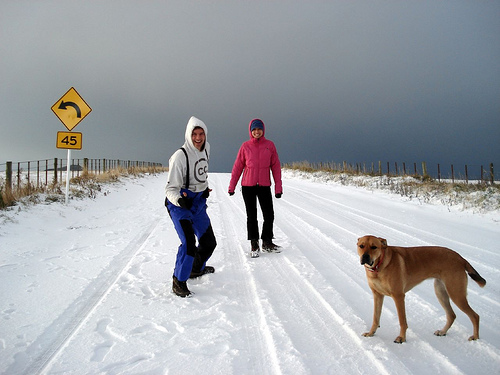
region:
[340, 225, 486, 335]
brown dog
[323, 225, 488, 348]
brown dog in white snow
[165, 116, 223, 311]
man standing in snow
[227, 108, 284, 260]
woman standing in snow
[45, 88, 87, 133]
yellow and black sign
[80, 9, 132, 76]
white clouds in blue sky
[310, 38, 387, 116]
white clouds in blue sky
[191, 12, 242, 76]
white clouds in blue sky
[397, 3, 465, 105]
white clouds in blue sky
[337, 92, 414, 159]
white clouds in blue sky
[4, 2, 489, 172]
The sky is over cast.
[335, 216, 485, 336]
The dog is brown.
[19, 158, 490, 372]
The ground is snow covered.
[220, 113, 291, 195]
Her jacket is pink.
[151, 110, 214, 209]
His jacket is white.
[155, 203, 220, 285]
His pants are blue.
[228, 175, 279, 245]
Her pants are black.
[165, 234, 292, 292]
Their boots are black.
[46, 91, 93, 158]
The sign is yellow.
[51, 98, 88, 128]
The arrow is black.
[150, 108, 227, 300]
A man in snow clothes striking a pose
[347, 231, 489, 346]
An unhappy looking dog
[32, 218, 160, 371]
Tire tracks in the snow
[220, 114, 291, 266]
A woman smiling at the camera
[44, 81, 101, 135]
A sign signalling an upcoming turn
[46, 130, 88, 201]
A sign stating the speed limit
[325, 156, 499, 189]
A small fence lining the road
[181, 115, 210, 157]
Man's face protected by a hood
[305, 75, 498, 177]
A very dark patch of sky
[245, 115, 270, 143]
Woman wearing a hat and a hood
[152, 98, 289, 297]
two people on snow covered road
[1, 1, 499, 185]
dark grey colored sky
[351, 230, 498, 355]
dog on a snow covered road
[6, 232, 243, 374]
footprints in the snow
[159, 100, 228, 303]
man in a white jacket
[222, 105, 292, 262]
woman in a pink jacket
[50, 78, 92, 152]
yellow and black road signs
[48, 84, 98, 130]
sign with a black arrow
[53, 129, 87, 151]
sign with number 45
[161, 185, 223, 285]
blue and black pants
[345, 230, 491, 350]
dog standing in the snow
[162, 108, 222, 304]
person in a white hoodie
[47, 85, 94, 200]
street sign on a pole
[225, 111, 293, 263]
woman in a pink coat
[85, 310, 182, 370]
footprints in the snow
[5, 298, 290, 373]
tire tracks in the snow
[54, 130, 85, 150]
number 45 on the sign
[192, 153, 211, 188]
"CC" on the hoodie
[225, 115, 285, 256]
woman wearing black pants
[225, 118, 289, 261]
woman wearing a blue hat